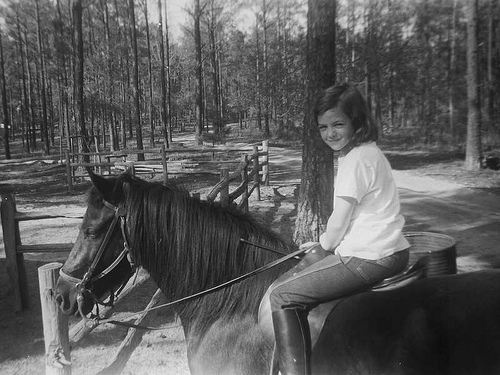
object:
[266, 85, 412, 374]
girl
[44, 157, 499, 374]
pony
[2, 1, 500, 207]
area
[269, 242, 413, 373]
saddle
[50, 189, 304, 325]
halter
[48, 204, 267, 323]
bridle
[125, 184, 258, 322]
mane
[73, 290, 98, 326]
bit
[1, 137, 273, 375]
fence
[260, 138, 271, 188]
post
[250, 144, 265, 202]
post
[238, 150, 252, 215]
post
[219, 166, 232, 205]
post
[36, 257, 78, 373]
post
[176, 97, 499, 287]
road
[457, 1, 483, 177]
trees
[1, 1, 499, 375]
picture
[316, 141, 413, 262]
shirt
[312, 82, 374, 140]
hair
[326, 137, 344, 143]
smile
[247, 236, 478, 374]
reins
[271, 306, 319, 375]
boot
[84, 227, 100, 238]
eye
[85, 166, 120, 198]
ear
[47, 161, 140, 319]
head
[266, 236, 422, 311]
jeans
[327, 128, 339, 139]
nose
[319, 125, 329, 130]
eye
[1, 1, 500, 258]
background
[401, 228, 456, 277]
can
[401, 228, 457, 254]
rim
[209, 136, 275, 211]
corner